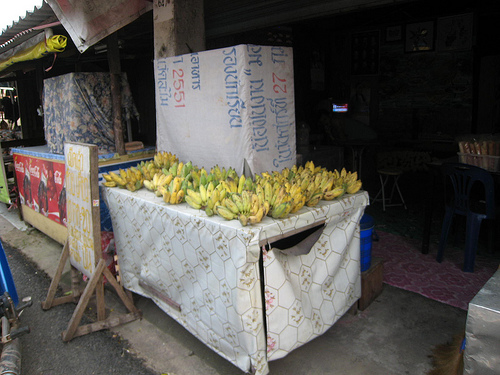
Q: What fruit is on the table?
A: Bananas.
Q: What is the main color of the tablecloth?
A: White.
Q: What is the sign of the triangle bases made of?
A: Wood.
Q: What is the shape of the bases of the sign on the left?
A: Triangle.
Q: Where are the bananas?
A: On table.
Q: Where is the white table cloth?
A: Under bananas.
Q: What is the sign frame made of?
A: Wood.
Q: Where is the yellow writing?
A: White sign.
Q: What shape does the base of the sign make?
A: Triangle.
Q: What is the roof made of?
A: Metal.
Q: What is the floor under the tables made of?
A: Concrete.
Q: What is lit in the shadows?
A: Tv.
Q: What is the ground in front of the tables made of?
A: Asphalt.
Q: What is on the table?
A: Bananas.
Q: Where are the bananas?
A: On the table.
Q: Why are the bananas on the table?
A: To sell.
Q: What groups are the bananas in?
A: Bunches.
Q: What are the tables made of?
A: Wood.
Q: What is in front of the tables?
A: A sign.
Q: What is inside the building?
A: Chairs and tables.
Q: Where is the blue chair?
A: Inside the building.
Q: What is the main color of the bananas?
A: Yellow.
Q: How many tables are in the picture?
A: Two.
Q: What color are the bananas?
A: Yellow.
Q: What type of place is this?
A: A market.